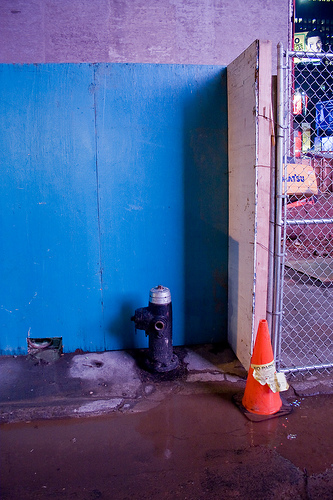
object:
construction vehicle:
[281, 162, 317, 195]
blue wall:
[0, 62, 228, 351]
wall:
[227, 40, 274, 373]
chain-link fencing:
[274, 43, 332, 378]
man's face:
[303, 31, 324, 57]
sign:
[291, 29, 330, 60]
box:
[280, 164, 316, 194]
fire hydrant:
[131, 286, 180, 373]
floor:
[0, 340, 333, 499]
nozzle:
[154, 317, 165, 333]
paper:
[249, 356, 290, 392]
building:
[0, 0, 333, 499]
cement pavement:
[0, 352, 333, 499]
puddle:
[0, 388, 333, 489]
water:
[0, 389, 332, 499]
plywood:
[93, 58, 228, 350]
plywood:
[2, 59, 100, 352]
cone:
[241, 320, 284, 418]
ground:
[0, 370, 333, 499]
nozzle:
[131, 305, 150, 332]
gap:
[25, 334, 63, 365]